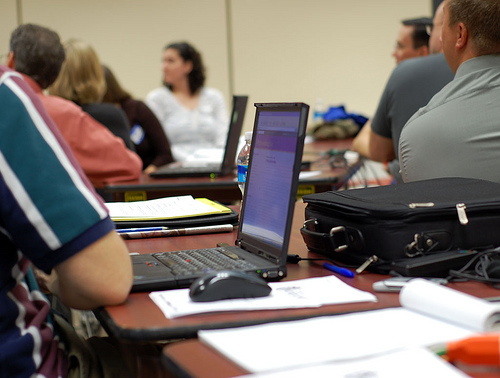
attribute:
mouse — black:
[188, 262, 269, 307]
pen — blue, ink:
[316, 248, 359, 281]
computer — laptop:
[101, 98, 311, 297]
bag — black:
[299, 167, 498, 288]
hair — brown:
[178, 40, 206, 102]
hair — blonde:
[68, 35, 108, 101]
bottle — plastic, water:
[310, 93, 320, 144]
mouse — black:
[192, 257, 268, 303]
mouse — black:
[182, 262, 273, 300]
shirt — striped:
[0, 65, 124, 355]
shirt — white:
[138, 81, 232, 179]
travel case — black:
[289, 167, 500, 289]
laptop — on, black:
[122, 95, 308, 298]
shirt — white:
[149, 87, 250, 178]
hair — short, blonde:
[42, 36, 115, 103]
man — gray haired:
[2, 21, 149, 188]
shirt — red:
[13, 66, 151, 188]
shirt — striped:
[0, 76, 119, 376]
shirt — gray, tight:
[372, 54, 452, 168]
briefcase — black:
[296, 168, 496, 282]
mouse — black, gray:
[185, 266, 274, 313]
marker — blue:
[309, 246, 361, 280]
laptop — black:
[145, 91, 252, 179]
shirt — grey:
[392, 61, 496, 177]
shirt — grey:
[370, 51, 457, 146]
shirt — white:
[144, 87, 234, 167]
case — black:
[301, 157, 498, 276]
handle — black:
[289, 210, 362, 250]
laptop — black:
[98, 77, 356, 367]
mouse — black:
[179, 253, 335, 337]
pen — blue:
[302, 248, 352, 294]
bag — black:
[283, 171, 491, 291]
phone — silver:
[351, 254, 447, 322]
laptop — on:
[163, 100, 313, 248]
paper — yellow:
[160, 180, 250, 239]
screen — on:
[216, 90, 326, 250]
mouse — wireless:
[183, 229, 283, 310]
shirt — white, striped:
[0, 60, 119, 283]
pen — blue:
[322, 259, 392, 295]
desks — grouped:
[93, 103, 400, 371]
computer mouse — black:
[185, 272, 276, 307]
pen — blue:
[315, 254, 364, 286]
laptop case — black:
[295, 165, 498, 283]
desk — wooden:
[70, 194, 497, 359]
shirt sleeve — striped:
[6, 71, 122, 265]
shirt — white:
[146, 84, 244, 176]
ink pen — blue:
[312, 249, 359, 283]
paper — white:
[148, 278, 386, 321]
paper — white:
[155, 269, 378, 319]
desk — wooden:
[68, 178, 488, 363]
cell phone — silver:
[364, 271, 445, 298]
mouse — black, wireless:
[186, 263, 270, 298]